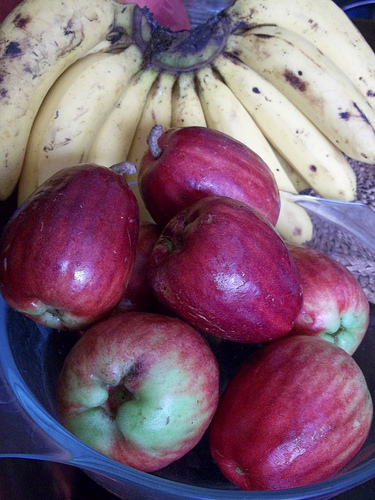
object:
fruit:
[0, 1, 375, 493]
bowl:
[2, 193, 375, 499]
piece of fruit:
[153, 196, 305, 348]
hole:
[98, 376, 135, 422]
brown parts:
[276, 66, 351, 123]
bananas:
[0, 0, 373, 247]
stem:
[132, 3, 230, 73]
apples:
[0, 124, 374, 496]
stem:
[147, 125, 164, 157]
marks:
[158, 276, 231, 338]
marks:
[61, 354, 208, 467]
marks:
[276, 66, 374, 140]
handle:
[1, 365, 70, 463]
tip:
[277, 197, 317, 248]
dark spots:
[279, 65, 312, 96]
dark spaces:
[139, 35, 228, 74]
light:
[54, 256, 92, 286]